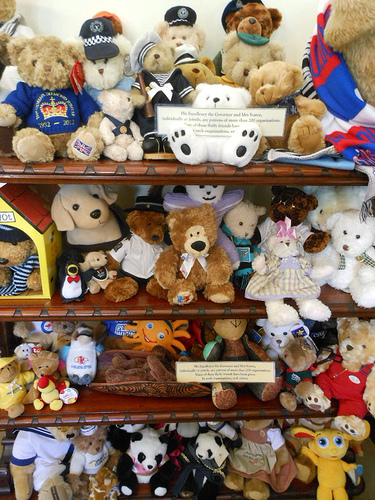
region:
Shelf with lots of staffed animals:
[0, 0, 367, 489]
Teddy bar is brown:
[146, 197, 240, 305]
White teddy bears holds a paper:
[141, 75, 285, 185]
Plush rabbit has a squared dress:
[244, 216, 334, 330]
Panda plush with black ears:
[103, 418, 180, 494]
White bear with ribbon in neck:
[306, 205, 372, 308]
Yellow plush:
[290, 422, 359, 497]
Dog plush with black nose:
[46, 183, 124, 247]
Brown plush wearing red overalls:
[290, 303, 372, 432]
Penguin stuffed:
[52, 252, 85, 307]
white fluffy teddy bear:
[256, 318, 306, 357]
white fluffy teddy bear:
[313, 209, 372, 304]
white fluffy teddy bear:
[155, 83, 262, 160]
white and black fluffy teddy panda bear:
[117, 431, 172, 494]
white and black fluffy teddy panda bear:
[180, 429, 227, 493]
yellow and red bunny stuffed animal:
[290, 425, 355, 497]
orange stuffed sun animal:
[123, 316, 188, 352]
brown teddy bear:
[67, 424, 120, 484]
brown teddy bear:
[26, 349, 60, 381]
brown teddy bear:
[83, 249, 115, 292]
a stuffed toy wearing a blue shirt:
[7, 32, 71, 172]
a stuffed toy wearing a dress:
[246, 222, 316, 326]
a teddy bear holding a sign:
[160, 80, 264, 182]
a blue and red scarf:
[307, 30, 357, 176]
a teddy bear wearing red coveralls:
[300, 319, 370, 426]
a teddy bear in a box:
[0, 187, 51, 313]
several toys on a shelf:
[5, 9, 363, 165]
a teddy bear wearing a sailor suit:
[126, 35, 186, 128]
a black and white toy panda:
[103, 428, 174, 493]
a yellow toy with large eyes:
[292, 426, 357, 498]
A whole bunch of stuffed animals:
[14, 49, 355, 349]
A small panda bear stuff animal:
[118, 428, 175, 488]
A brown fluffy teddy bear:
[165, 203, 235, 300]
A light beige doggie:
[51, 184, 125, 241]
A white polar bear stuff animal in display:
[173, 80, 255, 174]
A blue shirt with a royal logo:
[6, 78, 99, 133]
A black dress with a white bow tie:
[130, 69, 194, 106]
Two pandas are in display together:
[119, 430, 228, 493]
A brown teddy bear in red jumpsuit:
[323, 318, 373, 406]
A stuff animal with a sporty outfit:
[296, 30, 368, 110]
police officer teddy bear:
[58, 17, 162, 146]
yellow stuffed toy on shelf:
[285, 415, 374, 499]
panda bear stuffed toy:
[113, 424, 193, 495]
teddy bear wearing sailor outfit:
[12, 428, 93, 499]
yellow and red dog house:
[0, 185, 65, 317]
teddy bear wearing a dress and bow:
[249, 205, 327, 331]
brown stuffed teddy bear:
[152, 202, 254, 301]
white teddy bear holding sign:
[135, 73, 295, 184]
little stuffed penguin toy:
[50, 258, 92, 303]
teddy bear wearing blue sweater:
[0, 19, 116, 191]